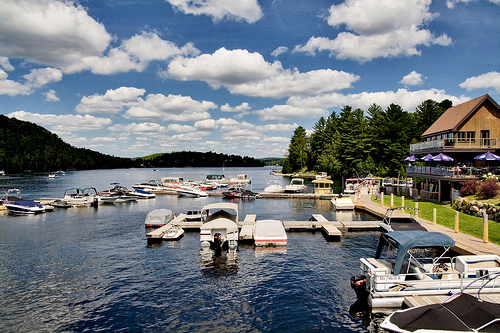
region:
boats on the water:
[27, 158, 258, 208]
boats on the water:
[7, 156, 222, 226]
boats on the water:
[17, 148, 252, 228]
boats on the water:
[25, 160, 235, 217]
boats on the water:
[25, 165, 207, 207]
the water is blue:
[50, 237, 157, 311]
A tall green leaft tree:
[284, 122, 306, 167]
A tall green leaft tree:
[382, 102, 414, 169]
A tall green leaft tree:
[344, 105, 374, 170]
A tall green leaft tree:
[362, 98, 385, 153]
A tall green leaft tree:
[311, 117, 329, 164]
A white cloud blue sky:
[90, 77, 152, 116]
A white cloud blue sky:
[168, 80, 235, 131]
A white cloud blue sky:
[252, 100, 291, 156]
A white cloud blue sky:
[355, 74, 436, 101]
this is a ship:
[8, 183, 48, 225]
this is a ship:
[42, 169, 110, 234]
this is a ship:
[134, 193, 172, 238]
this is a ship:
[213, 155, 256, 214]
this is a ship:
[91, 170, 153, 230]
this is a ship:
[239, 195, 279, 271]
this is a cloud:
[151, 50, 243, 90]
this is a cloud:
[273, 64, 342, 99]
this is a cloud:
[21, 13, 93, 79]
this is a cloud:
[136, 88, 202, 143]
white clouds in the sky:
[166, 44, 361, 98]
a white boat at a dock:
[198, 199, 241, 254]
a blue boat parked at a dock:
[0, 185, 57, 222]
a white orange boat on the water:
[130, 176, 207, 197]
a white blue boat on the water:
[349, 227, 499, 317]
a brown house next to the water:
[406, 93, 498, 204]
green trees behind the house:
[270, 99, 462, 182]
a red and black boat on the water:
[220, 183, 262, 203]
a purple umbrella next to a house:
[405, 153, 418, 171]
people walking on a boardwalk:
[352, 186, 365, 206]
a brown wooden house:
[410, 77, 498, 179]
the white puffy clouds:
[142, 25, 291, 120]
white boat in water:
[199, 200, 238, 246]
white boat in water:
[356, 228, 496, 313]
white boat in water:
[328, 193, 351, 208]